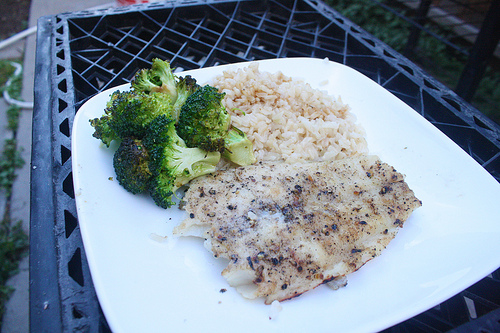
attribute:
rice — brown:
[202, 55, 371, 182]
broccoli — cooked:
[89, 54, 254, 204]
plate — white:
[66, 69, 496, 329]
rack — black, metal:
[115, 15, 270, 54]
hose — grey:
[0, 22, 36, 113]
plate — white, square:
[80, 167, 210, 332]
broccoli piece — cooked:
[112, 117, 219, 204]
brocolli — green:
[89, 57, 254, 210]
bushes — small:
[423, 31, 453, 59]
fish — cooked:
[205, 106, 407, 253]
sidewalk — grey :
[1, 0, 135, 330]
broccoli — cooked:
[99, 66, 249, 198]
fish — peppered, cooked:
[169, 148, 424, 305]